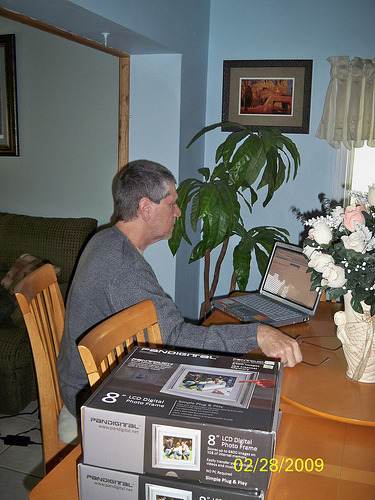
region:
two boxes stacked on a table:
[74, 343, 288, 498]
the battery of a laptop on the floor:
[3, 432, 35, 448]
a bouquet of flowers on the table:
[297, 180, 373, 382]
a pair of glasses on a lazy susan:
[289, 333, 346, 368]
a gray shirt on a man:
[56, 225, 257, 414]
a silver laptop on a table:
[214, 240, 324, 326]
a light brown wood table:
[28, 291, 372, 498]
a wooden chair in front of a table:
[12, 262, 77, 471]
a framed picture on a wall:
[216, 56, 323, 141]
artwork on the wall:
[212, 54, 312, 139]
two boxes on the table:
[68, 348, 310, 498]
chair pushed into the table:
[70, 299, 219, 460]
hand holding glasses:
[255, 322, 342, 373]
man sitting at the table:
[13, 155, 325, 465]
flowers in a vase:
[292, 178, 373, 386]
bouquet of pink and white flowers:
[299, 185, 374, 320]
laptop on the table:
[209, 241, 325, 331]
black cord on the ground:
[0, 401, 50, 453]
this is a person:
[48, 139, 302, 435]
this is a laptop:
[211, 232, 338, 327]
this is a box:
[77, 337, 369, 497]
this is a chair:
[8, 259, 69, 448]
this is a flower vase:
[301, 193, 373, 397]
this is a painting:
[214, 44, 320, 132]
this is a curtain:
[314, 53, 372, 149]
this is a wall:
[133, 7, 220, 108]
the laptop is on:
[226, 247, 321, 327]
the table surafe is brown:
[306, 432, 367, 486]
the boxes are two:
[83, 355, 295, 496]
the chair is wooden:
[87, 309, 163, 362]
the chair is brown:
[84, 308, 164, 369]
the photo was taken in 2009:
[232, 447, 334, 483]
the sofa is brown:
[29, 221, 67, 241]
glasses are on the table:
[278, 326, 313, 358]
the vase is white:
[330, 307, 373, 373]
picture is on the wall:
[218, 58, 305, 134]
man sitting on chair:
[51, 158, 306, 413]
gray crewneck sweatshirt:
[64, 227, 299, 375]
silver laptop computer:
[215, 238, 332, 340]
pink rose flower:
[335, 201, 366, 234]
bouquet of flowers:
[303, 191, 373, 384]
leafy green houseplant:
[166, 114, 287, 324]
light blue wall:
[11, 3, 369, 316]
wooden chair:
[15, 264, 118, 498]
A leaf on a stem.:
[232, 235, 254, 290]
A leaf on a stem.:
[256, 248, 267, 271]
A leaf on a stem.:
[260, 234, 278, 250]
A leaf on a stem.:
[268, 147, 278, 207]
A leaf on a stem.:
[259, 156, 274, 191]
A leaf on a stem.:
[277, 141, 295, 179]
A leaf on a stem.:
[197, 181, 226, 217]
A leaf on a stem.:
[199, 164, 211, 182]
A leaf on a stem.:
[209, 159, 232, 179]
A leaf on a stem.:
[161, 169, 200, 255]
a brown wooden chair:
[8, 255, 96, 425]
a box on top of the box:
[76, 317, 260, 462]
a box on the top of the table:
[75, 440, 224, 498]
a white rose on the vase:
[320, 262, 340, 283]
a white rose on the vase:
[309, 249, 331, 266]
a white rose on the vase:
[316, 213, 336, 239]